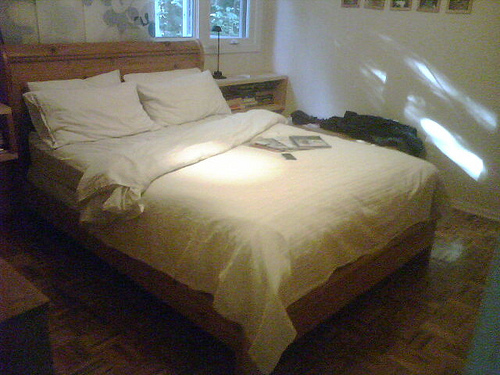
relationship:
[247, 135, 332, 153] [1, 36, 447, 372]
books on bed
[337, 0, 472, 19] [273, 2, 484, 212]
art on wall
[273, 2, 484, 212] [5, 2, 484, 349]
wall of bedroom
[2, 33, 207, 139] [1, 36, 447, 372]
headboard behind bed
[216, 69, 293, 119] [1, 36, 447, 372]
night stand next to bed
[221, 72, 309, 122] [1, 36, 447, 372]
bookshelf next to bed